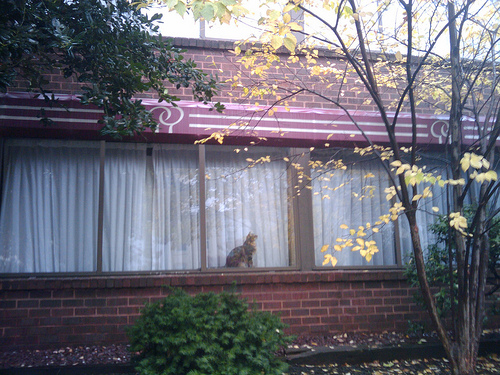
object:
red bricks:
[63, 297, 83, 307]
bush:
[120, 280, 297, 374]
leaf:
[428, 205, 440, 215]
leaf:
[74, 349, 88, 363]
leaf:
[15, 360, 30, 367]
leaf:
[308, 346, 315, 352]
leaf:
[480, 326, 491, 337]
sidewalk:
[0, 330, 499, 374]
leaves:
[329, 257, 340, 269]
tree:
[0, 0, 227, 145]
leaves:
[411, 360, 423, 367]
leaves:
[381, 362, 388, 368]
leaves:
[368, 360, 380, 366]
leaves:
[364, 253, 373, 263]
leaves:
[423, 367, 433, 374]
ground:
[0, 330, 499, 374]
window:
[100, 140, 202, 276]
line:
[187, 122, 430, 136]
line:
[1, 117, 100, 127]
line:
[464, 132, 499, 140]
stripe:
[189, 114, 428, 129]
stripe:
[461, 126, 499, 131]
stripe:
[0, 102, 105, 114]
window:
[206, 143, 294, 272]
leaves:
[207, 107, 214, 113]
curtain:
[101, 145, 289, 273]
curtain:
[0, 138, 102, 273]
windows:
[313, 149, 399, 270]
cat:
[223, 231, 260, 268]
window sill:
[206, 266, 296, 271]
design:
[147, 105, 184, 134]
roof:
[0, 92, 499, 147]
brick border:
[0, 267, 408, 291]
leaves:
[394, 166, 405, 178]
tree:
[121, 0, 499, 374]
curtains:
[309, 157, 404, 267]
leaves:
[282, 36, 297, 53]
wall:
[0, 268, 499, 356]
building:
[0, 33, 499, 354]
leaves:
[223, 330, 239, 339]